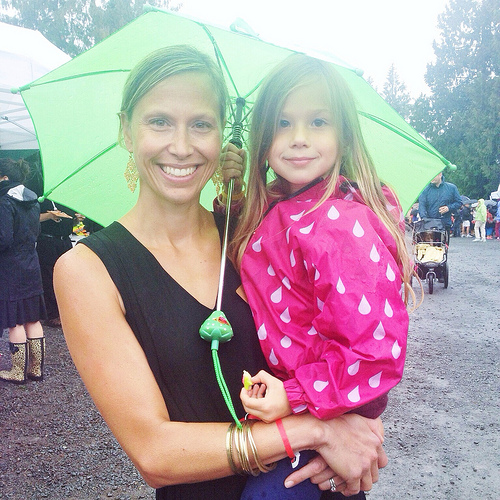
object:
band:
[276, 418, 296, 462]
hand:
[240, 370, 287, 423]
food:
[242, 370, 254, 391]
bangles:
[247, 419, 277, 473]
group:
[222, 417, 269, 477]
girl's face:
[268, 76, 338, 183]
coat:
[239, 176, 410, 420]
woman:
[0, 159, 45, 384]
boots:
[1, 341, 28, 385]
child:
[220, 54, 424, 500]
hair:
[226, 53, 423, 313]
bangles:
[243, 419, 261, 477]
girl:
[53, 44, 387, 500]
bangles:
[226, 423, 244, 477]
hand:
[318, 415, 388, 496]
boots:
[28, 337, 46, 381]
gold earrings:
[124, 152, 141, 193]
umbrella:
[9, 5, 458, 430]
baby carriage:
[410, 220, 448, 295]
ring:
[329, 478, 337, 492]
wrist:
[301, 413, 335, 450]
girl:
[232, 44, 415, 498]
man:
[419, 171, 462, 284]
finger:
[319, 476, 345, 490]